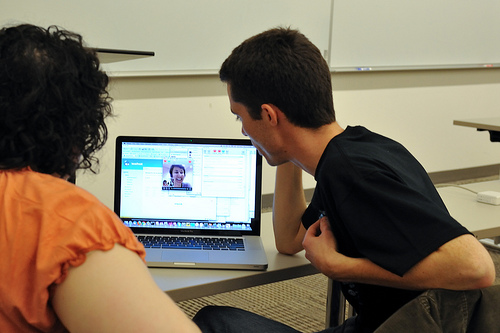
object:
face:
[173, 167, 185, 183]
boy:
[169, 163, 186, 187]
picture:
[161, 156, 193, 193]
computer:
[118, 133, 270, 271]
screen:
[119, 140, 256, 231]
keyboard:
[134, 235, 247, 252]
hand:
[300, 217, 336, 281]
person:
[192, 25, 494, 333]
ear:
[259, 104, 278, 127]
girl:
[0, 15, 202, 333]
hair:
[0, 23, 113, 179]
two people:
[1, 20, 494, 333]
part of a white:
[132, 9, 221, 52]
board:
[108, 7, 212, 39]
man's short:
[215, 25, 336, 130]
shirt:
[300, 126, 477, 333]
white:
[474, 187, 496, 208]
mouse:
[477, 190, 500, 206]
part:
[447, 169, 499, 255]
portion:
[285, 279, 314, 316]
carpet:
[272, 280, 315, 309]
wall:
[383, 85, 435, 142]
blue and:
[109, 47, 195, 92]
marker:
[103, 43, 255, 141]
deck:
[118, 139, 328, 330]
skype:
[126, 144, 193, 231]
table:
[463, 173, 498, 215]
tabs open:
[123, 220, 251, 230]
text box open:
[201, 154, 256, 196]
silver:
[161, 249, 209, 264]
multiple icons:
[123, 220, 254, 229]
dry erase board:
[114, 15, 241, 25]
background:
[74, 5, 482, 64]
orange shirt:
[0, 166, 144, 333]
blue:
[354, 65, 370, 71]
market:
[354, 64, 374, 77]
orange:
[484, 64, 493, 67]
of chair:
[370, 275, 500, 333]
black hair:
[218, 26, 336, 129]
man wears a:
[298, 124, 476, 323]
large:
[100, 4, 449, 44]